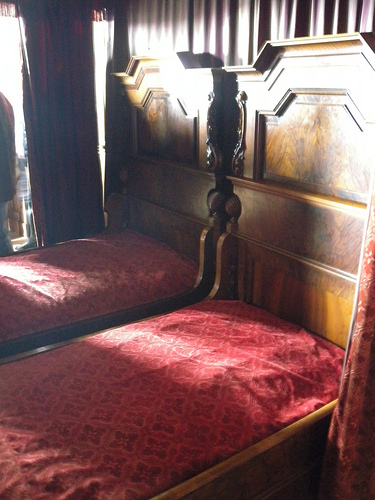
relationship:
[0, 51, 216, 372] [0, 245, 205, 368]
bed has rail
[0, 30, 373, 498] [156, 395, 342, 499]
bed has frame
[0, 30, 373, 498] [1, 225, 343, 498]
bed has bed spread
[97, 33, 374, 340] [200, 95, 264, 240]
head board has decoration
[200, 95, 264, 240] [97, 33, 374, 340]
decoration on head board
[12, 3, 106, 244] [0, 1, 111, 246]
curtain on window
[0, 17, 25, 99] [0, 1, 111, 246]
sky outside window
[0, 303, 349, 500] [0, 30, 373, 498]
sheet on bed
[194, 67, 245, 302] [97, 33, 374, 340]
finials are on head board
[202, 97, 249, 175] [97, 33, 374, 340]
carving on head board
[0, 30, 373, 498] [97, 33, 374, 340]
beds have head boards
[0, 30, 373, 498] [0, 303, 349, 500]
beds have sheets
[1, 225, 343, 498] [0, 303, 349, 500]
pattern on sheet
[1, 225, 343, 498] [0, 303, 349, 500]
design on sheet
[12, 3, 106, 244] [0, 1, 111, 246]
curtain covering window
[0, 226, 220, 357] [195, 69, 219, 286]
bed has post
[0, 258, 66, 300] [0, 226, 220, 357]
sunlight on sheet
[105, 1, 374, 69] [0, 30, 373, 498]
drapes are behind bed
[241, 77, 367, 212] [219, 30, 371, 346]
design on head board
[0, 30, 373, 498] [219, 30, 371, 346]
bed has head board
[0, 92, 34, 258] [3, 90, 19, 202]
person has shirt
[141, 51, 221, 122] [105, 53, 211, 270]
sunlight on head board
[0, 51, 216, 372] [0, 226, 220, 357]
bed has sheet